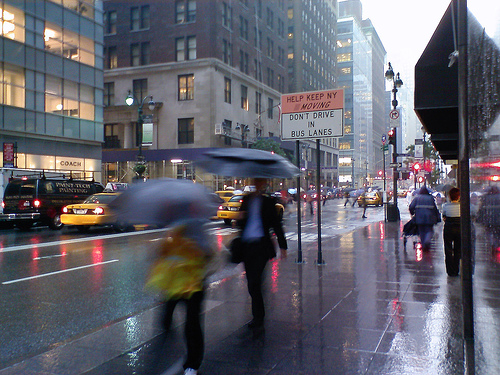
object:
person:
[409, 183, 442, 252]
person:
[440, 187, 462, 277]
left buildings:
[0, 0, 105, 218]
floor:
[0, 229, 465, 374]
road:
[0, 166, 500, 375]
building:
[102, 0, 407, 195]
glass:
[467, 0, 500, 373]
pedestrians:
[137, 200, 222, 374]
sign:
[279, 87, 346, 141]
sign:
[389, 109, 399, 120]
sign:
[142, 124, 154, 146]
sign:
[2, 141, 14, 168]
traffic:
[0, 167, 414, 230]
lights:
[91, 206, 105, 216]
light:
[411, 162, 423, 171]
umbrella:
[322, 186, 331, 189]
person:
[322, 189, 327, 205]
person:
[343, 191, 352, 206]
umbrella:
[341, 187, 356, 191]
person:
[306, 193, 315, 216]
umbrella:
[304, 190, 316, 195]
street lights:
[384, 62, 404, 88]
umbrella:
[106, 177, 225, 226]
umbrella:
[187, 148, 305, 180]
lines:
[1, 259, 120, 285]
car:
[61, 181, 132, 231]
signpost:
[279, 89, 346, 139]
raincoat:
[144, 226, 203, 300]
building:
[0, 0, 106, 192]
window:
[44, 20, 99, 66]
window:
[44, 71, 93, 120]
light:
[383, 61, 405, 221]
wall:
[105, 7, 330, 195]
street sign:
[412, 0, 500, 165]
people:
[225, 174, 290, 329]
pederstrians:
[297, 186, 368, 218]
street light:
[124, 88, 157, 111]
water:
[472, 26, 500, 90]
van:
[0, 177, 105, 231]